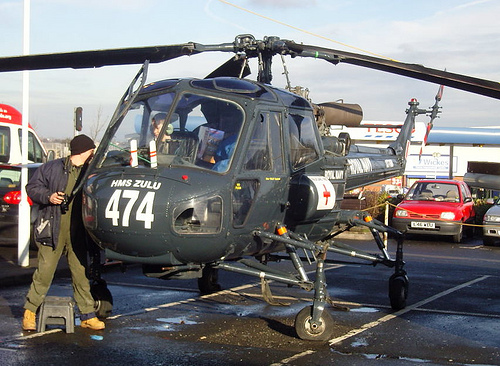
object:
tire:
[294, 305, 334, 341]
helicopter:
[0, 33, 499, 343]